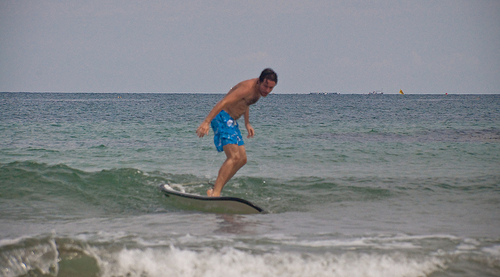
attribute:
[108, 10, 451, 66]
sky — gray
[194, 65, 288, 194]
man — surfing, leaning, balancing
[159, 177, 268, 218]
surfboard — white, black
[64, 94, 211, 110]
water — blue, calm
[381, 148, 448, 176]
water — green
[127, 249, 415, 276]
water — white, foamy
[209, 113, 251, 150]
shorts — blue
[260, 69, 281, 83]
hair — brown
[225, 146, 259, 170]
knees — bent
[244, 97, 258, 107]
chesthair — brown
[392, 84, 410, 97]
object — yellow, far, small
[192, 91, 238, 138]
arm — extended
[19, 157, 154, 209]
wave — small